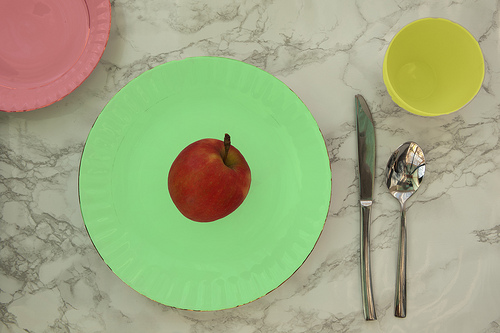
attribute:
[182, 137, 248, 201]
apple — red, round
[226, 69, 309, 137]
plate — green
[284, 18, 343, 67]
table — white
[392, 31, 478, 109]
cup — yellow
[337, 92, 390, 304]
knife — silver